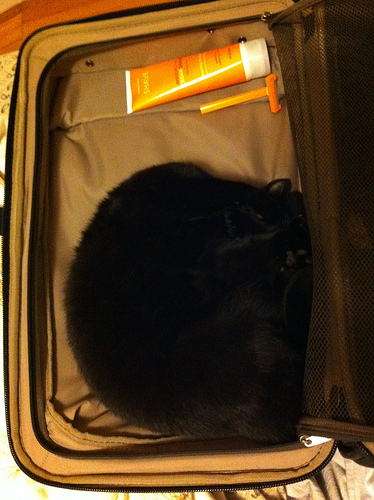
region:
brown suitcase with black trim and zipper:
[4, 4, 349, 491]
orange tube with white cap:
[120, 31, 268, 109]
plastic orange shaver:
[193, 72, 280, 111]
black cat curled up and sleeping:
[58, 151, 301, 441]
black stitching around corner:
[40, 386, 132, 448]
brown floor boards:
[0, 0, 170, 49]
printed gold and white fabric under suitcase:
[0, 432, 213, 495]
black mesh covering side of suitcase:
[267, 1, 363, 438]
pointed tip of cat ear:
[261, 171, 295, 194]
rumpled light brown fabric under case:
[261, 445, 369, 493]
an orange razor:
[202, 81, 277, 113]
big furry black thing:
[107, 198, 298, 432]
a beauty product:
[126, 42, 264, 90]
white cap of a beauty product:
[243, 38, 263, 79]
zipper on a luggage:
[300, 436, 330, 443]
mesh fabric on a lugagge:
[282, 22, 332, 82]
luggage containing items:
[21, 5, 300, 462]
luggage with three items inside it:
[28, 2, 330, 488]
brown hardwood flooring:
[2, 1, 45, 26]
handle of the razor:
[206, 90, 266, 114]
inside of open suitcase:
[0, 0, 371, 494]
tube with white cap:
[125, 36, 270, 115]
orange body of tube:
[124, 45, 247, 113]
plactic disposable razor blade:
[199, 74, 282, 120]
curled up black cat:
[67, 161, 309, 445]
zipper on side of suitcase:
[23, 443, 337, 495]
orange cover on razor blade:
[264, 73, 281, 112]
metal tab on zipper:
[302, 433, 333, 446]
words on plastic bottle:
[135, 48, 235, 96]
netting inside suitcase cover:
[269, 4, 370, 429]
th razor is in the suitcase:
[194, 71, 284, 120]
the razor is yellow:
[197, 65, 285, 127]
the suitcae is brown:
[182, 462, 233, 477]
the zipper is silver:
[296, 432, 330, 447]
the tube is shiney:
[116, 80, 241, 89]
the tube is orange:
[113, 30, 272, 120]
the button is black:
[79, 56, 95, 71]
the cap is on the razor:
[262, 70, 285, 114]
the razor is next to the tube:
[83, 41, 283, 127]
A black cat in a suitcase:
[0, 144, 371, 460]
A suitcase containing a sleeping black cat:
[3, 11, 372, 493]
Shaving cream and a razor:
[110, 32, 287, 122]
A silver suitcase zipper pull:
[288, 432, 340, 452]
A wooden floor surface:
[11, 0, 92, 27]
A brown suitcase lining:
[77, 120, 265, 161]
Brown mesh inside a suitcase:
[318, 43, 369, 417]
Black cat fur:
[106, 255, 166, 376]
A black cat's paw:
[272, 240, 307, 276]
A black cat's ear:
[262, 170, 296, 202]